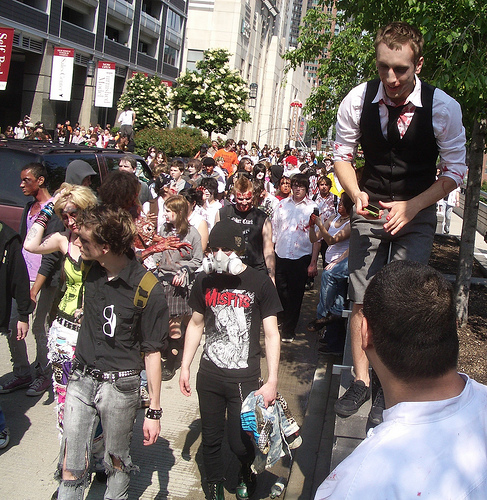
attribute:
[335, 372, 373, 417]
shoe — black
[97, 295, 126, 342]
sunlgasses — black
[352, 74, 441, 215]
vest — black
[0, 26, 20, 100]
banner — red and white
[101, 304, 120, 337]
sunglasses — black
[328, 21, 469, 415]
man — brown-haired, black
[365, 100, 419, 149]
tie — black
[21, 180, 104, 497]
person — black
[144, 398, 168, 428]
bracelet —  black 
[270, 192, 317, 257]
shirt — white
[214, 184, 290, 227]
sunglasses — black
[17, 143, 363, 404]
people — standing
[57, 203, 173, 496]
man — black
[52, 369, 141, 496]
jeans — ripped